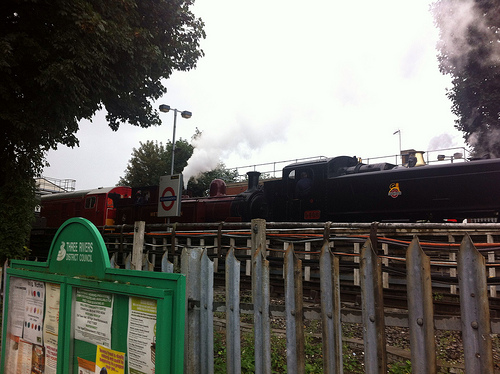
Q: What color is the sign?
A: Green.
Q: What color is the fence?
A: Brown.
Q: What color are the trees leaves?
A: Green.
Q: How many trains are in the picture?
A: One.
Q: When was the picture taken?
A: During the day.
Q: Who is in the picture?
A: The train conductor.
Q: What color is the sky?
A: Grey.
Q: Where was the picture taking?
A: At the train yard.